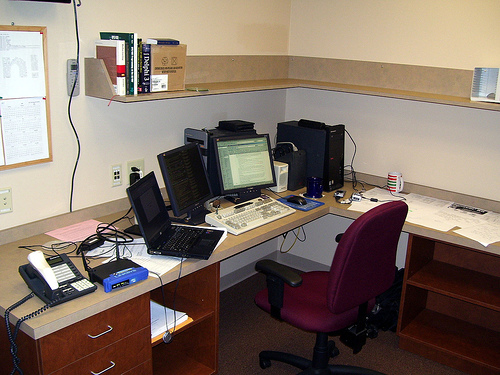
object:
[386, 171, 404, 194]
cup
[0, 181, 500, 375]
desk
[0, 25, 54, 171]
board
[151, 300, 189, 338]
papers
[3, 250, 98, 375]
telephone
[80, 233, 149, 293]
computer router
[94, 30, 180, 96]
books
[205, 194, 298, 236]
keyboard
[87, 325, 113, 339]
handle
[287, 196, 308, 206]
computer mouse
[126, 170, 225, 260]
laptop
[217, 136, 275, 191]
computer monitor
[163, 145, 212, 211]
computer monitor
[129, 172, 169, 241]
computer monitor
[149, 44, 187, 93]
cardboard box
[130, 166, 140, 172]
outlet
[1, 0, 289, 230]
wall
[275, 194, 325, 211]
mousepad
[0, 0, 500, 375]
office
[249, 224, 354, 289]
arms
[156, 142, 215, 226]
computer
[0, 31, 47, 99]
paper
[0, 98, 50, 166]
paper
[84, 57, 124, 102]
end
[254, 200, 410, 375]
chair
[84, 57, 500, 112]
shelf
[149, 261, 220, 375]
shelf